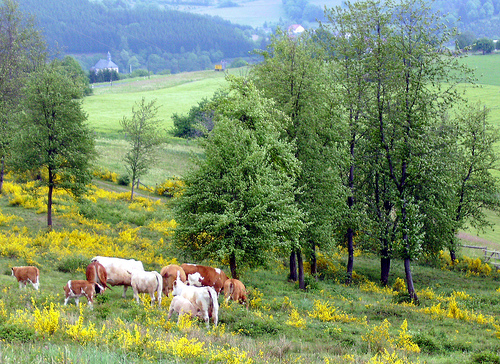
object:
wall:
[371, 149, 413, 189]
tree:
[0, 0, 100, 225]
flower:
[285, 309, 306, 329]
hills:
[0, 0, 251, 73]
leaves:
[225, 143, 247, 161]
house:
[92, 51, 118, 76]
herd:
[11, 256, 250, 331]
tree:
[165, 0, 500, 306]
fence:
[462, 245, 500, 272]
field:
[1, 0, 500, 362]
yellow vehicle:
[215, 65, 222, 69]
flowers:
[308, 277, 500, 364]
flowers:
[0, 294, 264, 364]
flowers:
[0, 172, 186, 268]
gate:
[482, 246, 499, 272]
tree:
[116, 96, 167, 200]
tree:
[0, 0, 267, 77]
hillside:
[0, 0, 500, 364]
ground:
[17, 283, 490, 361]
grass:
[0, 52, 500, 364]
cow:
[11, 256, 250, 331]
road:
[94, 178, 500, 248]